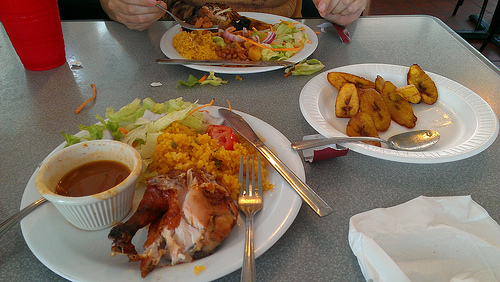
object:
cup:
[1, 0, 77, 80]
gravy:
[53, 158, 130, 195]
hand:
[108, 0, 171, 31]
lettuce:
[105, 96, 193, 124]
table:
[0, 15, 498, 280]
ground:
[348, 202, 360, 217]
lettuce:
[147, 57, 330, 86]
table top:
[1, 13, 496, 280]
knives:
[155, 56, 335, 218]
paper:
[288, 117, 365, 184]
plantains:
[121, 47, 462, 203]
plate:
[57, 17, 499, 223]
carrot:
[235, 25, 305, 52]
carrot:
[276, 15, 298, 27]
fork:
[152, 4, 219, 33]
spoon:
[289, 127, 447, 155]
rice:
[147, 121, 272, 191]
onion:
[243, 24, 273, 38]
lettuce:
[266, 17, 289, 53]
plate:
[294, 54, 485, 168]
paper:
[336, 191, 497, 281]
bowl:
[26, 131, 153, 236]